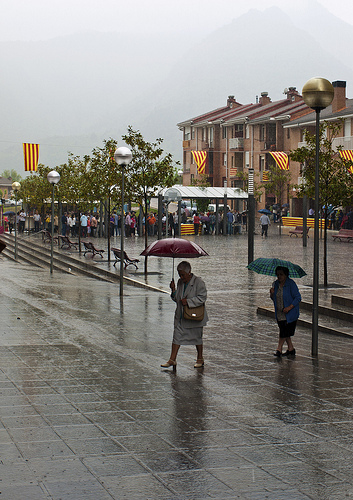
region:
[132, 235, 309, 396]
two women walking in the rain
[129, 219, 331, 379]
two women walking with umbrellas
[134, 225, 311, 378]
two women holding umbrellas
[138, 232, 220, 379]
a woman holding a red umbrella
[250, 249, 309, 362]
a woman holding a green umbrella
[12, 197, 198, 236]
a large crowd of people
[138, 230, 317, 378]
two women wearing dresses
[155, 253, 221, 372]
a woman wearing a dress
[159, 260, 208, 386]
a woman carrying a purse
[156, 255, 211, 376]
a woman with a brown purse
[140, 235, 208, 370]
woman walking in rain with umbrella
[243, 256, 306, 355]
second woman in blue walking in rain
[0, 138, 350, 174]
string of yellow and red flags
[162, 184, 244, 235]
structure to protect from weather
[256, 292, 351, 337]
three cement stairs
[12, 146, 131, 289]
row of tall lights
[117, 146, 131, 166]
round light at top of pole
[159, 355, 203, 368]
tan colored high heel shoes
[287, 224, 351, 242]
two benches to right hand of picture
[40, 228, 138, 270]
long row of benches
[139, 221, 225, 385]
woman holding an umbrella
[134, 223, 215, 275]
the umbrella is red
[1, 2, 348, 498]
it is raining in the scene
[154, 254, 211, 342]
woman's jacket is gray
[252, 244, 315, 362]
woman holding an umbrella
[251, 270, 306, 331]
woman's jacket is blue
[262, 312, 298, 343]
woman's skirt is black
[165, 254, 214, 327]
woman holding a purse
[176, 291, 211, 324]
the purse is brown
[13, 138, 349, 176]
flags are red and yellow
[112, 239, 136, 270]
a bench sitting outside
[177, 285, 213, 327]
a woman holding a purse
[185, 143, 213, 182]
a flag hanging on a pole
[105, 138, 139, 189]
a light on a pole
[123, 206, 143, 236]
people standing in line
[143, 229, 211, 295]
a woman holding an umbrella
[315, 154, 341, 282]
a tree planted in a park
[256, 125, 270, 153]
a window on a building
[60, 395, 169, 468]
a stone walkway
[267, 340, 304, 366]
a pair of black shoes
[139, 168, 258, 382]
a woman holding an a unbrella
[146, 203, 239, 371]
a woman holding a red unbrella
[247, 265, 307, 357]
a woman wearing a blue jacket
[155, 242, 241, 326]
a woman wearing a grey jacket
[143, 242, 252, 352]
a woman wearing a grey skirt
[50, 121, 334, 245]
people standing near a building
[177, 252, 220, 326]
a woman carrying a brown purse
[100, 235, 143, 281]
a brown bench near a tree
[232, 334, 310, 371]
a woman wearing black shoes